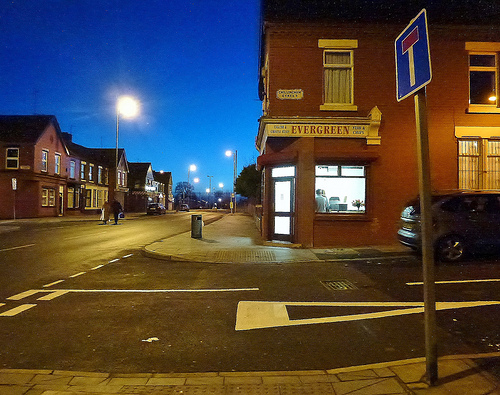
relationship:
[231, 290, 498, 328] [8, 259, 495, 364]
lines are on street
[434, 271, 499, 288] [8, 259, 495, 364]
lines are on street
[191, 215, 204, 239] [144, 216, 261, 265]
garbage can on sidewalk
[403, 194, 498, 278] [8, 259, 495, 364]
car parked on street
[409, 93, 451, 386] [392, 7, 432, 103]
pole holding up sign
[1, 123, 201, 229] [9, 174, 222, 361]
buildings along street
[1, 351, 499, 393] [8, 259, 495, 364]
sidewalk along street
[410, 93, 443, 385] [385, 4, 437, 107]
pole holding sign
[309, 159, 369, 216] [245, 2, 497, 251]
window on building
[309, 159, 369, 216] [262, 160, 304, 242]
window next to door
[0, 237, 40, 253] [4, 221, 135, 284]
lines are on street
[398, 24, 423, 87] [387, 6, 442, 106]
t on sign